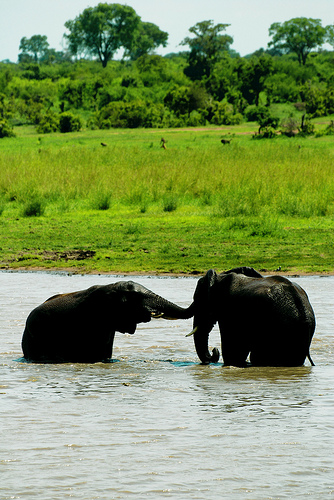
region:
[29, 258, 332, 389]
There are two elephants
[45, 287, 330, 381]
The elephants are in the water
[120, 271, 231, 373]
The elephants have tusks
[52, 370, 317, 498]
The water is murky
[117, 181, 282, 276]
The grass is green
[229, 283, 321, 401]
The elephants are dark in color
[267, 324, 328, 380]
The elephants have tails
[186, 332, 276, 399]
the elephant has a long trunk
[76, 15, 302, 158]
There are trees in the distance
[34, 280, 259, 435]
The elephants have big ears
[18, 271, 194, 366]
A baby elephant standing in a pool of water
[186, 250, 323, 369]
An elephant standing in a river.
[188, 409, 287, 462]
A section of a body of water.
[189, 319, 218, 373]
The trunk of an elephant.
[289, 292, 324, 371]
the tale of an elephant.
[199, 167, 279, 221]
A patch of green grass on the side of a river.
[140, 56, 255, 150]
A lush green forest of trees.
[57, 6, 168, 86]
A tall leaf fllled tree.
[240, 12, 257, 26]
A section of hazy blue sky.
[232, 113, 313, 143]
Wild brush on a shoreline.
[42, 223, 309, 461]
two elephants playing in the water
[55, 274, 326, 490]
two elephants in the river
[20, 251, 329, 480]
two elephants cleaning each other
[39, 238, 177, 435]
elephant with trunk out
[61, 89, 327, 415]
very green grass next to river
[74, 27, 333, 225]
animals next to the elephants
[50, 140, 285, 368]
tufts of grass sticking up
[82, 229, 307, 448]
elephants playing in the water with each other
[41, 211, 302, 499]
elephants playing together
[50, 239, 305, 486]
elephants half submerged in water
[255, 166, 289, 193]
part of some grass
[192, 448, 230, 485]
part of a water body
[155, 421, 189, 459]
part of some waves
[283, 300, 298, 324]
back of an elephant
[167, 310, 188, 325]
part of a trunk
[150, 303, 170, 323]
part of a tusk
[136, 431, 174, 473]
part of a water wave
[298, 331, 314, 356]
part of a tail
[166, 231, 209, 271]
part of a grass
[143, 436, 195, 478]
part of a water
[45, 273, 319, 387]
Two elephants stand in the water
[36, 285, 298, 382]
One of the elephants touches the other with its trunk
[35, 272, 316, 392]
Both elephants have white tusks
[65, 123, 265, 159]
Small gazelle graze in the field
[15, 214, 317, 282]
Green grass lines the shore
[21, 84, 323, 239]
A large field of green grass is surrounded by bushes on one side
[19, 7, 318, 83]
Trees rise above the bushes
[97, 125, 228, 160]
The gazelle are brown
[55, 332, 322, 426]
The water is murky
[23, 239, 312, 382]
The elephants are about fifteen feet off shore